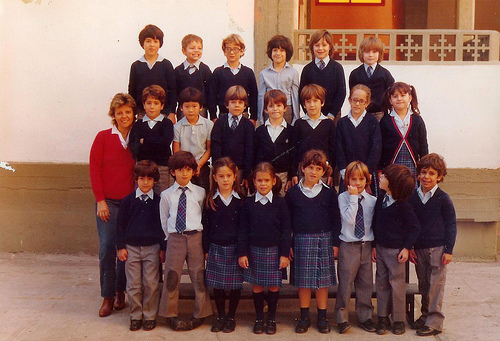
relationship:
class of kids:
[142, 27, 442, 211] [142, 20, 433, 181]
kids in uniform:
[142, 20, 433, 181] [129, 53, 176, 85]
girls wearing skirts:
[214, 158, 338, 332] [203, 246, 337, 289]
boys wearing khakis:
[127, 160, 202, 303] [125, 250, 206, 337]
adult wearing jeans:
[88, 90, 137, 317] [94, 223, 120, 296]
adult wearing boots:
[88, 90, 137, 317] [93, 296, 125, 320]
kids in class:
[142, 20, 433, 181] [142, 27, 442, 211]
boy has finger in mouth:
[335, 160, 369, 335] [357, 184, 362, 196]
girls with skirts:
[214, 158, 338, 332] [203, 246, 337, 289]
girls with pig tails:
[214, 158, 338, 332] [380, 80, 414, 93]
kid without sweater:
[261, 29, 297, 94] [99, 153, 120, 181]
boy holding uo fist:
[333, 160, 379, 334] [345, 182, 358, 205]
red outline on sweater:
[398, 126, 410, 153] [386, 120, 398, 152]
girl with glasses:
[331, 82, 375, 155] [348, 97, 368, 106]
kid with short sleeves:
[261, 29, 297, 94] [176, 127, 181, 142]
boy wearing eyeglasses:
[335, 160, 369, 335] [225, 47, 241, 52]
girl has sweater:
[222, 46, 245, 56] [99, 153, 120, 181]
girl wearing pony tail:
[222, 46, 245, 56] [325, 161, 333, 176]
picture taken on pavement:
[142, 27, 442, 211] [461, 283, 488, 326]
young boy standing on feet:
[355, 35, 394, 87] [409, 310, 446, 338]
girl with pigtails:
[222, 46, 245, 56] [274, 165, 283, 191]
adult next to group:
[82, 81, 144, 324] [142, 27, 442, 211]